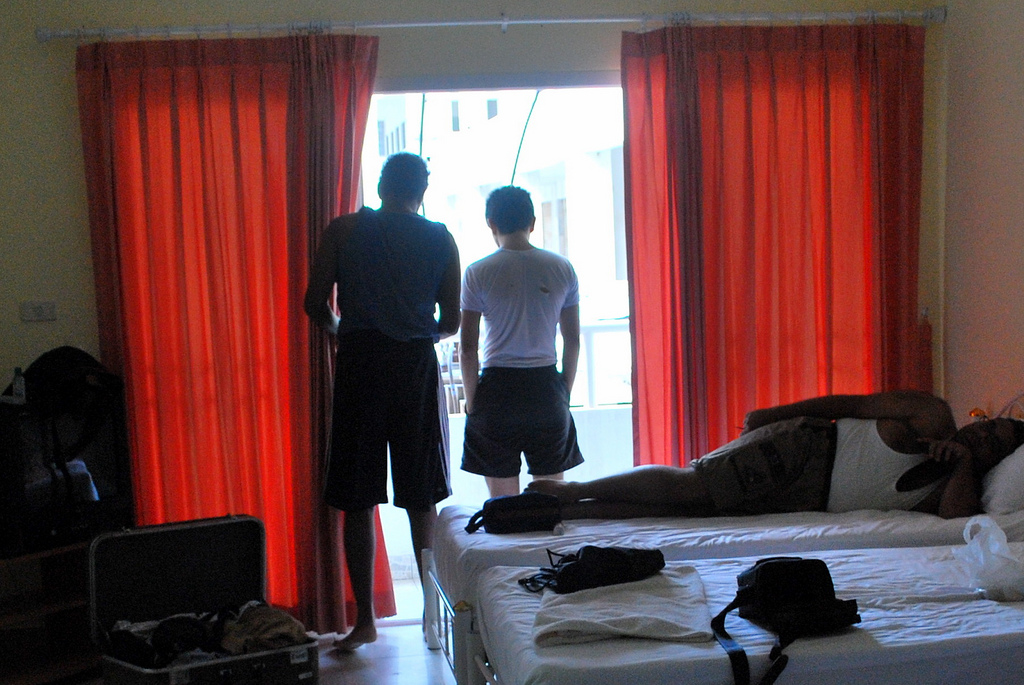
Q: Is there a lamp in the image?
A: No, there are no lamps.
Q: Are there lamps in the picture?
A: No, there are no lamps.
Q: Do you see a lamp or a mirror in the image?
A: No, there are no lamps or mirrors.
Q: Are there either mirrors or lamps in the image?
A: No, there are no lamps or mirrors.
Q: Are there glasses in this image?
A: No, there are no glasses.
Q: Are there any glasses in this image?
A: No, there are no glasses.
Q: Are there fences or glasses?
A: No, there are no glasses or fences.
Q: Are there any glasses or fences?
A: No, there are no glasses or fences.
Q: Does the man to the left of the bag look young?
A: Yes, the man is young.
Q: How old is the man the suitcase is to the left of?
A: The man is young.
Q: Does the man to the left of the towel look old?
A: No, the man is young.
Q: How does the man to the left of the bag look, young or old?
A: The man is young.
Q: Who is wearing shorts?
A: The man is wearing shorts.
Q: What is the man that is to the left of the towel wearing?
A: The man is wearing shorts.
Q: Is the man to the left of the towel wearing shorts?
A: Yes, the man is wearing shorts.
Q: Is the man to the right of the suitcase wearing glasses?
A: No, the man is wearing shorts.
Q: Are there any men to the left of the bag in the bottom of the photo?
A: Yes, there is a man to the left of the bag.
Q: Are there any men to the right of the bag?
A: No, the man is to the left of the bag.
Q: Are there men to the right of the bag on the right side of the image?
A: No, the man is to the left of the bag.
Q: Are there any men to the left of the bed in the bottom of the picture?
A: Yes, there is a man to the left of the bed.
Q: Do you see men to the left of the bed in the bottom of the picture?
A: Yes, there is a man to the left of the bed.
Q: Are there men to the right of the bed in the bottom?
A: No, the man is to the left of the bed.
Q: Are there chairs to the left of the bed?
A: No, there is a man to the left of the bed.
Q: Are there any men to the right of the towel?
A: No, the man is to the left of the towel.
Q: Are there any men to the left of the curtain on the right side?
A: Yes, there is a man to the left of the curtain.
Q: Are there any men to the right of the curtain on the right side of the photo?
A: No, the man is to the left of the curtain.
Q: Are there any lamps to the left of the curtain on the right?
A: No, there is a man to the left of the curtain.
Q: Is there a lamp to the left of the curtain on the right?
A: No, there is a man to the left of the curtain.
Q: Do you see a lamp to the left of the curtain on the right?
A: No, there is a man to the left of the curtain.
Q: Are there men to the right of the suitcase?
A: Yes, there is a man to the right of the suitcase.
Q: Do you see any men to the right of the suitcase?
A: Yes, there is a man to the right of the suitcase.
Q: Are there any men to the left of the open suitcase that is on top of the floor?
A: No, the man is to the right of the suitcase.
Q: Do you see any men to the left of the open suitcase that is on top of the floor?
A: No, the man is to the right of the suitcase.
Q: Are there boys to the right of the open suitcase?
A: No, there is a man to the right of the suitcase.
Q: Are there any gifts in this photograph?
A: No, there are no gifts.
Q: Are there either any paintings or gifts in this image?
A: No, there are no gifts or paintings.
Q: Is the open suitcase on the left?
A: Yes, the suitcase is on the left of the image.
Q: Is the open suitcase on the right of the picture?
A: No, the suitcase is on the left of the image.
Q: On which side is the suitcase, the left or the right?
A: The suitcase is on the left of the image.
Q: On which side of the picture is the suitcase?
A: The suitcase is on the left of the image.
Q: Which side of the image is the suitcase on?
A: The suitcase is on the left of the image.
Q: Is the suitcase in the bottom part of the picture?
A: Yes, the suitcase is in the bottom of the image.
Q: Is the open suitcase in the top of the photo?
A: No, the suitcase is in the bottom of the image.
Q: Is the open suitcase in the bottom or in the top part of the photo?
A: The suitcase is in the bottom of the image.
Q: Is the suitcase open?
A: Yes, the suitcase is open.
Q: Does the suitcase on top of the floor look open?
A: Yes, the suitcase is open.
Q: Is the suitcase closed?
A: No, the suitcase is open.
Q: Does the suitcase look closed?
A: No, the suitcase is open.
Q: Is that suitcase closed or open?
A: The suitcase is open.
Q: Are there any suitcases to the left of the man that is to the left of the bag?
A: Yes, there is a suitcase to the left of the man.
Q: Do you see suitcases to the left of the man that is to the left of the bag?
A: Yes, there is a suitcase to the left of the man.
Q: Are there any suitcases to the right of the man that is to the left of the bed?
A: No, the suitcase is to the left of the man.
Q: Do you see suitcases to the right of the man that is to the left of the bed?
A: No, the suitcase is to the left of the man.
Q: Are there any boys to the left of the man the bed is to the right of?
A: No, there is a suitcase to the left of the man.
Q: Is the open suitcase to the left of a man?
A: Yes, the suitcase is to the left of a man.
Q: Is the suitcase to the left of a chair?
A: No, the suitcase is to the left of a man.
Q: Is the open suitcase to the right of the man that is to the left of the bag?
A: No, the suitcase is to the left of the man.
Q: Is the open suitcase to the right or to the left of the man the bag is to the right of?
A: The suitcase is to the left of the man.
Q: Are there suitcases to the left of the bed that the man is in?
A: Yes, there is a suitcase to the left of the bed.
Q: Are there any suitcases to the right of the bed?
A: No, the suitcase is to the left of the bed.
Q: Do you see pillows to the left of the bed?
A: No, there is a suitcase to the left of the bed.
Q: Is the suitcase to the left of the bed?
A: Yes, the suitcase is to the left of the bed.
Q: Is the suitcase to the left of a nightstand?
A: No, the suitcase is to the left of the bed.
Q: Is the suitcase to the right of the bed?
A: No, the suitcase is to the left of the bed.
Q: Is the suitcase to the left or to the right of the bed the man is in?
A: The suitcase is to the left of the bed.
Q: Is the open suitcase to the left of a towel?
A: Yes, the suitcase is to the left of a towel.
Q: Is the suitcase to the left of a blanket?
A: No, the suitcase is to the left of a towel.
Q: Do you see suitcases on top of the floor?
A: Yes, there is a suitcase on top of the floor.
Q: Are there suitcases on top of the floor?
A: Yes, there is a suitcase on top of the floor.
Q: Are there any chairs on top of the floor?
A: No, there is a suitcase on top of the floor.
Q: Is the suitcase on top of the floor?
A: Yes, the suitcase is on top of the floor.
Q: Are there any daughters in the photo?
A: No, there are no daughters.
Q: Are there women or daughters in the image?
A: No, there are no daughters or women.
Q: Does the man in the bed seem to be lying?
A: Yes, the man is lying.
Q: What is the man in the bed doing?
A: The man is lying.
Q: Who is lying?
A: The man is lying.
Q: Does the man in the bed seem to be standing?
A: No, the man is lying.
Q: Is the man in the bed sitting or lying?
A: The man is lying.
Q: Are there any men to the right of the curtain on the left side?
A: Yes, there is a man to the right of the curtain.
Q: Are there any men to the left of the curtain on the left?
A: No, the man is to the right of the curtain.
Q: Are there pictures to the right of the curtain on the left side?
A: No, there is a man to the right of the curtain.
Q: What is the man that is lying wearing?
A: The man is wearing shorts.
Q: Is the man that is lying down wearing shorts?
A: Yes, the man is wearing shorts.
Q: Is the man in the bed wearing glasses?
A: No, the man is wearing shorts.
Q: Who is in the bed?
A: The man is in the bed.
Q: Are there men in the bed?
A: Yes, there is a man in the bed.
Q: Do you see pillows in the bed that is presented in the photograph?
A: No, there is a man in the bed.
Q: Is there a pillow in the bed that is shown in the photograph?
A: No, there is a man in the bed.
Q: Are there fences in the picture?
A: No, there are no fences.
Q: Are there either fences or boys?
A: No, there are no fences or boys.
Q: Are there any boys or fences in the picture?
A: No, there are no fences or boys.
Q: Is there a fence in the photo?
A: No, there are no fences.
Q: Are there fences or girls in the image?
A: No, there are no fences or girls.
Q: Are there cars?
A: No, there are no cars.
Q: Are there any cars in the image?
A: No, there are no cars.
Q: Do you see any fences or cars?
A: No, there are no cars or fences.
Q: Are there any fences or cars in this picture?
A: No, there are no cars or fences.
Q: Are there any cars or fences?
A: No, there are no cars or fences.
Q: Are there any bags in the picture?
A: Yes, there is a bag.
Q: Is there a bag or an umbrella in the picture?
A: Yes, there is a bag.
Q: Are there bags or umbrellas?
A: Yes, there is a bag.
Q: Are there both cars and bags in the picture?
A: No, there is a bag but no cars.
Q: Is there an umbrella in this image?
A: No, there are no umbrellas.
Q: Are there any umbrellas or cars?
A: No, there are no umbrellas or cars.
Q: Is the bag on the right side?
A: Yes, the bag is on the right of the image.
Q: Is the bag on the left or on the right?
A: The bag is on the right of the image.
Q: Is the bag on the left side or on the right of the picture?
A: The bag is on the right of the image.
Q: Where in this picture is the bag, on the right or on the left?
A: The bag is on the right of the image.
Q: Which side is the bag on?
A: The bag is on the right of the image.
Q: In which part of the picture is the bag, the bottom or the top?
A: The bag is in the bottom of the image.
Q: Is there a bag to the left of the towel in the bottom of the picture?
A: No, the bag is to the right of the towel.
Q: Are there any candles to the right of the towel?
A: No, there is a bag to the right of the towel.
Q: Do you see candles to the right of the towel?
A: No, there is a bag to the right of the towel.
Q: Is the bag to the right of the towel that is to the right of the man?
A: Yes, the bag is to the right of the towel.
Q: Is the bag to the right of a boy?
A: No, the bag is to the right of the towel.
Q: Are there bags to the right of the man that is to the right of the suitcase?
A: Yes, there is a bag to the right of the man.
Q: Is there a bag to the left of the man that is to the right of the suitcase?
A: No, the bag is to the right of the man.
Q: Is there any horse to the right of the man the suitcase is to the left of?
A: No, there is a bag to the right of the man.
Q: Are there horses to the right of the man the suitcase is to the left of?
A: No, there is a bag to the right of the man.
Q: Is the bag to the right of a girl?
A: No, the bag is to the right of a man.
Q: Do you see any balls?
A: No, there are no balls.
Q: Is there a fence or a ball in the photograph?
A: No, there are no balls or fences.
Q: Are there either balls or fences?
A: No, there are no balls or fences.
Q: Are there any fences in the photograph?
A: No, there are no fences.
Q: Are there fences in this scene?
A: No, there are no fences.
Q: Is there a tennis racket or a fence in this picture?
A: No, there are no fences or rackets.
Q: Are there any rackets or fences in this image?
A: No, there are no fences or rackets.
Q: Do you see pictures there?
A: No, there are no pictures.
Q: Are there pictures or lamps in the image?
A: No, there are no pictures or lamps.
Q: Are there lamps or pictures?
A: No, there are no pictures or lamps.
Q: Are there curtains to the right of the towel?
A: No, the curtain is to the left of the towel.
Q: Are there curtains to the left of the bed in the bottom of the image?
A: Yes, there is a curtain to the left of the bed.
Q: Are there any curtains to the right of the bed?
A: No, the curtain is to the left of the bed.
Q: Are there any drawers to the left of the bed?
A: No, there is a curtain to the left of the bed.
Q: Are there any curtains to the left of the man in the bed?
A: Yes, there is a curtain to the left of the man.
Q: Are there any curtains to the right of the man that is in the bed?
A: No, the curtain is to the left of the man.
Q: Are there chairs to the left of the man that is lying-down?
A: No, there is a curtain to the left of the man.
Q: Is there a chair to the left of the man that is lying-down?
A: No, there is a curtain to the left of the man.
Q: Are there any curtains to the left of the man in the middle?
A: Yes, there is a curtain to the left of the man.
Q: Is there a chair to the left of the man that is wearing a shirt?
A: No, there is a curtain to the left of the man.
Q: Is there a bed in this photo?
A: Yes, there is a bed.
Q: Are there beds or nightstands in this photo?
A: Yes, there is a bed.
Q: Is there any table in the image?
A: No, there are no tables.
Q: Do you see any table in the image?
A: No, there are no tables.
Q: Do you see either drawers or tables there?
A: No, there are no tables or drawers.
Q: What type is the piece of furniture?
A: The piece of furniture is a bed.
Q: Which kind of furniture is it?
A: The piece of furniture is a bed.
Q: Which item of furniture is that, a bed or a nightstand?
A: This is a bed.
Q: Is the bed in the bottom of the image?
A: Yes, the bed is in the bottom of the image.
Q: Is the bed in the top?
A: No, the bed is in the bottom of the image.